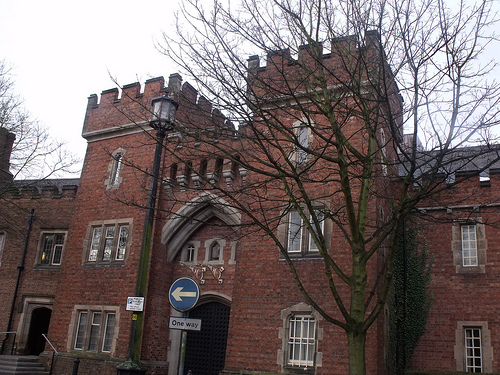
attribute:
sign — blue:
[165, 278, 202, 315]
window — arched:
[100, 145, 127, 192]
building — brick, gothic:
[250, 210, 400, 352]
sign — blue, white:
[164, 275, 226, 313]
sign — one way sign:
[170, 316, 201, 331]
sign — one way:
[168, 315, 203, 332]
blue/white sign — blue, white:
[169, 276, 200, 313]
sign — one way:
[168, 275, 198, 310]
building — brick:
[3, 30, 497, 373]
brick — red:
[93, 190, 123, 210]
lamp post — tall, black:
[138, 86, 163, 292]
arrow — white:
[168, 286, 197, 306]